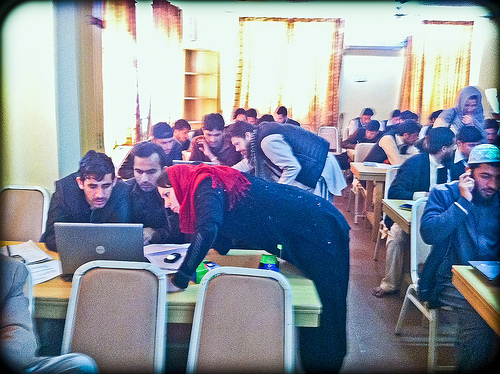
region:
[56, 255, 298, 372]
two empty chairs in a classroom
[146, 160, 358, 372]
a woman leaning over a table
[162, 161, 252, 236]
a woman's red head scarf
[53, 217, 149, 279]
a grey colored laptop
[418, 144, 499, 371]
a man holding a cell phone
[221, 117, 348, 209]
a man leaning over a table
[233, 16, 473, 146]
two yellow curtains in the back of the classroom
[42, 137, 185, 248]
two men looking at a screen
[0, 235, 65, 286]
paperwork on a table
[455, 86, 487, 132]
a woman's grey head scarf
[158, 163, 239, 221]
Red scarf on head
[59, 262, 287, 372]
Two chairs on front row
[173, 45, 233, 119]
three shelved bookcase in back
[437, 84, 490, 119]
Blue scarf on womans head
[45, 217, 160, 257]
laptop computer on table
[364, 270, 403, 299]
bare foot of man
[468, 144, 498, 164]
Green hat on mans head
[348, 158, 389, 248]
Wooden table in back of room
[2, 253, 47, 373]
Crossed arm of man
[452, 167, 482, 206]
Finger in mans ear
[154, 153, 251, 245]
Red head scarf with fringe.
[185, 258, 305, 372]
Metal framed chair.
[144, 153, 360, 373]
Woman in a scarf.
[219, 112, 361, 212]
Man bending over a table.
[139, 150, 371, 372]
Woman bending over a table.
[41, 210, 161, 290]
Open silver lap top.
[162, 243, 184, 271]
Cell phone atop papers.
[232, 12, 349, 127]
Big window curtains.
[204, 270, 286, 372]
Brown seat back.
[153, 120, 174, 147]
Black hat on a man.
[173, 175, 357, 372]
the dress is black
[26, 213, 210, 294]
laptop on the table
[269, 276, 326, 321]
the table is green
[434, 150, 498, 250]
the man is holding his phone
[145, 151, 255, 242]
the scarf is red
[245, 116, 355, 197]
the vest is black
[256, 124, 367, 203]
the man is wearing a vest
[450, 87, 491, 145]
the hijab is gray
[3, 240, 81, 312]
the papers on the table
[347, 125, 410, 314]
the man is barefoot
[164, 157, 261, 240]
red scarf with tassels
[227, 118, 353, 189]
man in black vest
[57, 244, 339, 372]
two brown chairs with a gray frame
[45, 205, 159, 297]
gray laptop with dell logo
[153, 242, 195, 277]
computer mouse resting on table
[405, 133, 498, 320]
man talking on the phone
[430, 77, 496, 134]
woman standing in a headscarf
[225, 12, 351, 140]
golden curtains hanging in the window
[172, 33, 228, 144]
brown bookshelf standing in the corner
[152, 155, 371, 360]
woman leaning over the table